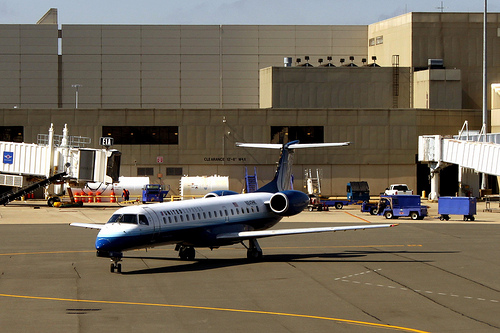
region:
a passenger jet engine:
[272, 190, 312, 212]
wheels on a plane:
[107, 261, 127, 271]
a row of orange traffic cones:
[70, 188, 123, 203]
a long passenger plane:
[62, 133, 394, 274]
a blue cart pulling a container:
[382, 190, 480, 223]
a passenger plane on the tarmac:
[55, 128, 394, 293]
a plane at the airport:
[0, 17, 357, 280]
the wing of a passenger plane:
[212, 210, 399, 251]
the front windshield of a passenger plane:
[102, 211, 152, 230]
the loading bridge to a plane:
[3, 143, 125, 188]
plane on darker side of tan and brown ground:
[7, 199, 497, 331]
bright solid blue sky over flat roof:
[2, 3, 497, 36]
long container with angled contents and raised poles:
[256, 43, 400, 109]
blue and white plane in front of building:
[71, 131, 396, 276]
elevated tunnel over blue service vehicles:
[378, 125, 493, 222]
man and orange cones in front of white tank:
[47, 168, 153, 206]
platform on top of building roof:
[2, 17, 413, 124]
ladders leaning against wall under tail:
[236, 137, 348, 208]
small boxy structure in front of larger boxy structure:
[373, 5, 495, 113]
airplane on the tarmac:
[55, 126, 412, 293]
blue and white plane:
[62, 121, 414, 288]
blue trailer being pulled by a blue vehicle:
[378, 184, 482, 224]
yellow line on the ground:
[1, 288, 436, 332]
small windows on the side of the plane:
[155, 200, 267, 227]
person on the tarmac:
[120, 185, 132, 204]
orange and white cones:
[63, 185, 123, 202]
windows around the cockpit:
[100, 208, 151, 228]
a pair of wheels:
[103, 260, 128, 275]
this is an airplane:
[52, 118, 402, 283]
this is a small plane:
[64, 130, 401, 285]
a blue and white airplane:
[68, 120, 394, 278]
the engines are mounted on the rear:
[189, 178, 310, 224]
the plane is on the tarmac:
[39, 135, 420, 293]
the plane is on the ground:
[65, 124, 401, 279]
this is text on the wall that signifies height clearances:
[200, 154, 254, 165]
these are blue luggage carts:
[384, 190, 482, 226]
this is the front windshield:
[107, 208, 154, 232]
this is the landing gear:
[91, 240, 280, 281]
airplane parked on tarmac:
[58, 137, 407, 282]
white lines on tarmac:
[330, 260, 497, 309]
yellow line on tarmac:
[7, 284, 429, 331]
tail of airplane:
[229, 132, 357, 193]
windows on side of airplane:
[160, 201, 269, 228]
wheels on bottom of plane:
[103, 257, 132, 277]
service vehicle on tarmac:
[355, 184, 432, 226]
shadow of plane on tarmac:
[113, 240, 469, 282]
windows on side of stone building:
[98, 118, 331, 148]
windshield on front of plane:
[101, 208, 150, 233]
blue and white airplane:
[72, 140, 397, 273]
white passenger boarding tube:
[417, 131, 497, 201]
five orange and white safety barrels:
[71, 189, 115, 203]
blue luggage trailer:
[438, 193, 473, 222]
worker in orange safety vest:
[119, 187, 131, 202]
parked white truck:
[382, 181, 414, 198]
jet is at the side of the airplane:
[260, 187, 310, 213]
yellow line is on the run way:
[0, 293, 434, 331]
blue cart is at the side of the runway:
[436, 195, 473, 223]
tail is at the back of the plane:
[226, 140, 351, 187]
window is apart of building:
[101, 122, 180, 145]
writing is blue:
[243, 198, 258, 205]